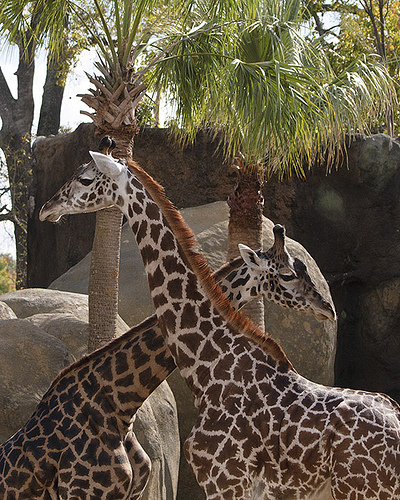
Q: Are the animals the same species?
A: Yes, all the animals are giraffes.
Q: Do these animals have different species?
A: No, all the animals are giraffes.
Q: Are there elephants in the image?
A: No, there are no elephants.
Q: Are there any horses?
A: No, there are no horses.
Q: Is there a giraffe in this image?
A: Yes, there is a giraffe.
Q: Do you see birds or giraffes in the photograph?
A: Yes, there is a giraffe.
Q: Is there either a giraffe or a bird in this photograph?
A: Yes, there is a giraffe.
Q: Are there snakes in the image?
A: No, there are no snakes.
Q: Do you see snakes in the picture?
A: No, there are no snakes.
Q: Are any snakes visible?
A: No, there are no snakes.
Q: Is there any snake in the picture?
A: No, there are no snakes.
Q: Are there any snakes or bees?
A: No, there are no snakes or bees.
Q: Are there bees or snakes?
A: No, there are no snakes or bees.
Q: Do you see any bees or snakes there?
A: No, there are no snakes or bees.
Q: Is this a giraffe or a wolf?
A: This is a giraffe.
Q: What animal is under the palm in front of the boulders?
A: The giraffe is under the palm.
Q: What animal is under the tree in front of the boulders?
A: The giraffe is under the palm.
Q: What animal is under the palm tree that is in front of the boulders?
A: The animal is a giraffe.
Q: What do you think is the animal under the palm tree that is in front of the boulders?
A: The animal is a giraffe.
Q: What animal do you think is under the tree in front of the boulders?
A: The animal is a giraffe.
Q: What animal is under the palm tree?
A: The animal is a giraffe.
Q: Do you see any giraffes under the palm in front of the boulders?
A: Yes, there is a giraffe under the palm tree.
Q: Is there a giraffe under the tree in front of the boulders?
A: Yes, there is a giraffe under the palm tree.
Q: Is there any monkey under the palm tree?
A: No, there is a giraffe under the palm tree.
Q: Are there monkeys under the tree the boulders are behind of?
A: No, there is a giraffe under the palm tree.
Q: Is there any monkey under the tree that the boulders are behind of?
A: No, there is a giraffe under the palm tree.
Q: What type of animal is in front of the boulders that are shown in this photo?
A: The animal is a giraffe.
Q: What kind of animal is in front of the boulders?
A: The animal is a giraffe.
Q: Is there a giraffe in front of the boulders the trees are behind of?
A: Yes, there is a giraffe in front of the boulders.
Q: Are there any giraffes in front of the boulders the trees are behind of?
A: Yes, there is a giraffe in front of the boulders.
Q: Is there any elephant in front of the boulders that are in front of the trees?
A: No, there is a giraffe in front of the boulders.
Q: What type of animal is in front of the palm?
A: The animal is a giraffe.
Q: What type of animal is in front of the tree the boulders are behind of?
A: The animal is a giraffe.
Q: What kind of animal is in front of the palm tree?
A: The animal is a giraffe.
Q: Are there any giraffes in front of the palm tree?
A: Yes, there is a giraffe in front of the palm tree.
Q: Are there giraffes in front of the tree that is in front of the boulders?
A: Yes, there is a giraffe in front of the palm tree.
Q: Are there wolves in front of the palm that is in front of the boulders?
A: No, there is a giraffe in front of the palm.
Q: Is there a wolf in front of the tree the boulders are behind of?
A: No, there is a giraffe in front of the palm.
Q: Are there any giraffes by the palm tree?
A: Yes, there is a giraffe by the palm tree.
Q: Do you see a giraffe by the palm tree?
A: Yes, there is a giraffe by the palm tree.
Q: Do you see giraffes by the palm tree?
A: Yes, there is a giraffe by the palm tree.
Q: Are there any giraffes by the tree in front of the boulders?
A: Yes, there is a giraffe by the palm tree.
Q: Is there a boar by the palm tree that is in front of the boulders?
A: No, there is a giraffe by the palm.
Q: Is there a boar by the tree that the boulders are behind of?
A: No, there is a giraffe by the palm.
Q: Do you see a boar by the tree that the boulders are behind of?
A: No, there is a giraffe by the palm.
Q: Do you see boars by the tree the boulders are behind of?
A: No, there is a giraffe by the palm.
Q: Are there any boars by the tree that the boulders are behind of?
A: No, there is a giraffe by the palm.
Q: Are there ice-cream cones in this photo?
A: No, there are no ice-cream cones.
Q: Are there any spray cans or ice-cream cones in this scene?
A: No, there are no ice-cream cones or spray cans.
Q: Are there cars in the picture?
A: No, there are no cars.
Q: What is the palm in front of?
A: The palm is in front of the boulders.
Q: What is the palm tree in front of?
A: The palm is in front of the boulders.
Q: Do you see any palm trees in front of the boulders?
A: Yes, there is a palm tree in front of the boulders.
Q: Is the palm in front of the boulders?
A: Yes, the palm is in front of the boulders.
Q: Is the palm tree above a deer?
A: No, the palm tree is above the giraffe.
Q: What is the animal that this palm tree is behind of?
A: The animal is a giraffe.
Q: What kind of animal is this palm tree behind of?
A: The palm tree is behind the giraffe.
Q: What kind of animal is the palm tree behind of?
A: The palm tree is behind the giraffe.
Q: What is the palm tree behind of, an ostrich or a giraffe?
A: The palm tree is behind a giraffe.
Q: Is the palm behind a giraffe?
A: Yes, the palm is behind a giraffe.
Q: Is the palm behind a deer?
A: No, the palm is behind a giraffe.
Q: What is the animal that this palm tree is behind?
A: The animal is a giraffe.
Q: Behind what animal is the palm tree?
A: The palm tree is behind the giraffe.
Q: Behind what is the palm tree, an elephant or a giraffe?
A: The palm tree is behind a giraffe.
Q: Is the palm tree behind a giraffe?
A: Yes, the palm tree is behind a giraffe.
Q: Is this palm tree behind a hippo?
A: No, the palm tree is behind a giraffe.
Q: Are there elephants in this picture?
A: No, there are no elephants.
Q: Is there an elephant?
A: No, there are no elephants.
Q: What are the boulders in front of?
A: The boulders are in front of the trees.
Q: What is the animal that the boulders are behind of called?
A: The animal is a giraffe.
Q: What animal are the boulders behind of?
A: The boulders are behind the giraffe.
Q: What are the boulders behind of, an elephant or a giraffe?
A: The boulders are behind a giraffe.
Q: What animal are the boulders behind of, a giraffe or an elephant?
A: The boulders are behind a giraffe.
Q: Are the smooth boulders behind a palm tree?
A: Yes, the boulders are behind a palm tree.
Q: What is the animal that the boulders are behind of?
A: The animal is a giraffe.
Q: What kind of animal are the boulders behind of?
A: The boulders are behind the giraffe.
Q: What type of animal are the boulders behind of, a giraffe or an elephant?
A: The boulders are behind a giraffe.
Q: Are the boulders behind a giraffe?
A: Yes, the boulders are behind a giraffe.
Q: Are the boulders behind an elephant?
A: No, the boulders are behind a giraffe.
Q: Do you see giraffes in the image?
A: Yes, there is a giraffe.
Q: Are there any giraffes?
A: Yes, there is a giraffe.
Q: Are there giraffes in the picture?
A: Yes, there is a giraffe.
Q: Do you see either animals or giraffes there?
A: Yes, there is a giraffe.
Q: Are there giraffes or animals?
A: Yes, there is a giraffe.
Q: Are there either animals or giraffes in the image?
A: Yes, there is a giraffe.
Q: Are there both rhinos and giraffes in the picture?
A: No, there is a giraffe but no rhinos.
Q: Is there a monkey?
A: No, there are no monkeys.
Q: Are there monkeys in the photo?
A: No, there are no monkeys.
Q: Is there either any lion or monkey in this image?
A: No, there are no monkeys or lions.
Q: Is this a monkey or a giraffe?
A: This is a giraffe.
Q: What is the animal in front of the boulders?
A: The animal is a giraffe.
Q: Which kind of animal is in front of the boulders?
A: The animal is a giraffe.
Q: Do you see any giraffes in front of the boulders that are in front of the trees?
A: Yes, there is a giraffe in front of the boulders.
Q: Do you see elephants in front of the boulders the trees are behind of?
A: No, there is a giraffe in front of the boulders.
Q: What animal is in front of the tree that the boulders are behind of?
A: The giraffe is in front of the palm tree.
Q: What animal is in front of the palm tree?
A: The giraffe is in front of the palm tree.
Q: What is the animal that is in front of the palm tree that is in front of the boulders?
A: The animal is a giraffe.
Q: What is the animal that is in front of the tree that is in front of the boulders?
A: The animal is a giraffe.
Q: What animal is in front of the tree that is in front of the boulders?
A: The animal is a giraffe.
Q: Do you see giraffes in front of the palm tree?
A: Yes, there is a giraffe in front of the palm tree.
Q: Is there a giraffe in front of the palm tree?
A: Yes, there is a giraffe in front of the palm tree.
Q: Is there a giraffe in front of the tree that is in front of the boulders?
A: Yes, there is a giraffe in front of the palm tree.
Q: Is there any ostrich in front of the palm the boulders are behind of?
A: No, there is a giraffe in front of the palm tree.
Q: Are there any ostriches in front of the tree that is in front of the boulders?
A: No, there is a giraffe in front of the palm tree.